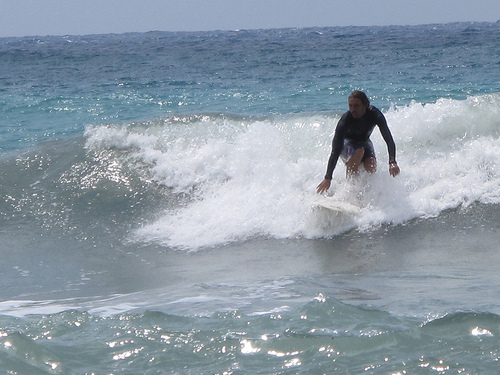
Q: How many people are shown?
A: 1.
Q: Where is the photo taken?
A: Ocean.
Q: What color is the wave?
A: White.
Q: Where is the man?
A: In the ocean.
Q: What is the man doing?
A: Surfing.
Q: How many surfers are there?
A: 1.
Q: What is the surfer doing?
A: Riding a wave.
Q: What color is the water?
A: Blue.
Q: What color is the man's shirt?
A: Black.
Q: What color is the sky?
A: Blue.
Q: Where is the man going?
A: Towards shore.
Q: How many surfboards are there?
A: 1.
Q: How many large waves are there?
A: 1.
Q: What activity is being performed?
A: Surfing.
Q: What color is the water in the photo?
A: Blue.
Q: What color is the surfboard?
A: White.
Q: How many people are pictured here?
A: One.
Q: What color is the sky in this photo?
A: Blue.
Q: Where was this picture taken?
A: Ocean.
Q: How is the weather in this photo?
A: Sunny.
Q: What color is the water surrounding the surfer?
A: White.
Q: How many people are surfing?
A: One.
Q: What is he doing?
A: Surfing.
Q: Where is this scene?
A: Beach.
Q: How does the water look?
A: Blue.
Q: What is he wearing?
A: Swim trunks.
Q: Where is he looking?
A: Straight.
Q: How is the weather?
A: Clear.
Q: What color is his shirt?
A: Black.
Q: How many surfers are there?
A: 1.